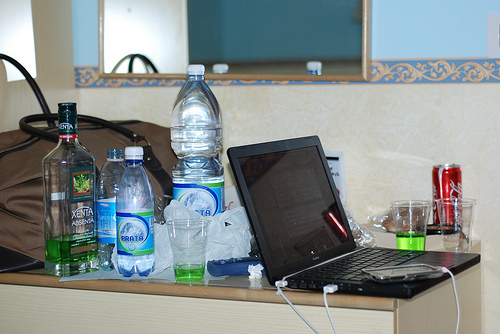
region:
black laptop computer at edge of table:
[228, 134, 480, 302]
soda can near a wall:
[430, 141, 463, 227]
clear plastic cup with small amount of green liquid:
[168, 218, 209, 281]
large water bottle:
[168, 63, 225, 215]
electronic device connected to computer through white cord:
[275, 262, 461, 332]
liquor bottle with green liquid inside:
[43, 100, 99, 276]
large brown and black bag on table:
[1, 112, 177, 284]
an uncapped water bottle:
[94, 146, 122, 266]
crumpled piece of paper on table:
[242, 262, 266, 289]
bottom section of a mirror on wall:
[88, 1, 386, 95]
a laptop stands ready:
[234, 113, 480, 332]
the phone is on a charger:
[355, 250, 473, 310]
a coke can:
[427, 147, 469, 227]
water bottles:
[97, 74, 232, 275]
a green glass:
[157, 215, 214, 283]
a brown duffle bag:
[12, 113, 205, 262]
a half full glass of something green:
[393, 195, 434, 251]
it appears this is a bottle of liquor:
[41, 89, 104, 289]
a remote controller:
[205, 251, 262, 281]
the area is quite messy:
[37, 57, 484, 322]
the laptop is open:
[222, 130, 463, 327]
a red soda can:
[424, 147, 484, 269]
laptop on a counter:
[225, 129, 479, 294]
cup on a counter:
[162, 209, 214, 290]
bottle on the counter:
[119, 148, 157, 278]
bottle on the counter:
[47, 88, 99, 268]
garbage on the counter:
[241, 258, 262, 284]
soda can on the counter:
[430, 160, 467, 235]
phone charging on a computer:
[364, 255, 441, 306]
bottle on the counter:
[166, 64, 226, 221]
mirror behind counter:
[215, 9, 415, 59]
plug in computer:
[317, 280, 342, 317]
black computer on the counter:
[227, 135, 484, 299]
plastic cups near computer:
[169, 198, 473, 284]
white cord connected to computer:
[274, 264, 461, 332]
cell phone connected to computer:
[365, 261, 445, 284]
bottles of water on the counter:
[117, 61, 225, 280]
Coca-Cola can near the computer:
[433, 162, 465, 224]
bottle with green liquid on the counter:
[43, 102, 95, 274]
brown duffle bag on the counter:
[0, 52, 179, 267]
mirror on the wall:
[99, 0, 370, 78]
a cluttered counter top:
[6, 235, 481, 312]